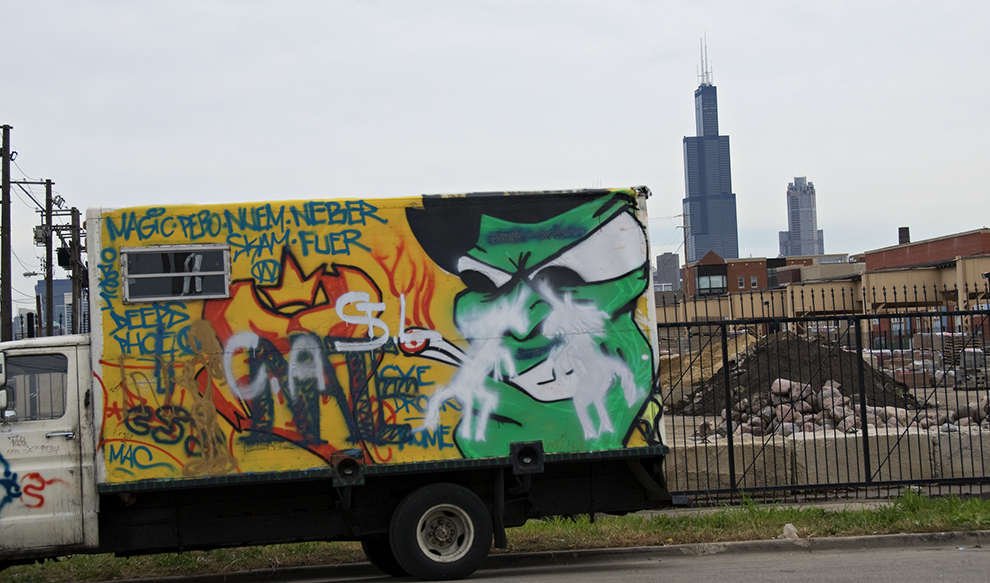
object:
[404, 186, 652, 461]
face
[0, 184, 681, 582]
truck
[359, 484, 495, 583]
wheels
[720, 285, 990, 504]
gate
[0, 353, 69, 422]
window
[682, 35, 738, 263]
building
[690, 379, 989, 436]
pile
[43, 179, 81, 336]
row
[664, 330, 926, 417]
dirt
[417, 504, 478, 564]
rim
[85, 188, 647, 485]
paint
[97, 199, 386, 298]
letters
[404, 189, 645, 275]
hair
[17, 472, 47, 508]
writing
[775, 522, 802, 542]
trash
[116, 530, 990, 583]
ground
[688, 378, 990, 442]
rocks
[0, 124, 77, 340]
poles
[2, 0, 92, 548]
side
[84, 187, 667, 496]
sign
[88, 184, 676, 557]
trailer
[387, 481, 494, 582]
tire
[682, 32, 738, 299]
tower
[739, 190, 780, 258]
distance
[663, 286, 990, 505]
fence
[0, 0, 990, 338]
sky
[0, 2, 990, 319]
clouds